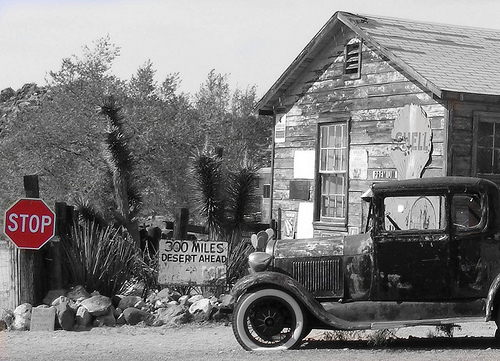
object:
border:
[51, 207, 57, 238]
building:
[253, 11, 498, 243]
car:
[230, 175, 500, 353]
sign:
[369, 102, 434, 180]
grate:
[278, 253, 345, 295]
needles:
[95, 94, 139, 217]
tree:
[0, 27, 195, 225]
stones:
[190, 300, 208, 320]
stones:
[85, 293, 109, 314]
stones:
[155, 288, 171, 302]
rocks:
[1, 82, 50, 114]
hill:
[1, 81, 218, 228]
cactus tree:
[98, 94, 143, 223]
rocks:
[5, 299, 38, 330]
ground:
[0, 320, 497, 359]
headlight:
[247, 251, 270, 272]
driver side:
[364, 176, 499, 304]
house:
[236, 8, 499, 263]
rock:
[78, 294, 116, 316]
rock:
[118, 306, 143, 328]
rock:
[152, 303, 193, 326]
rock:
[187, 295, 215, 322]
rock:
[8, 299, 33, 330]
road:
[0, 318, 499, 358]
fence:
[9, 173, 352, 312]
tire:
[223, 276, 314, 351]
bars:
[316, 120, 347, 174]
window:
[313, 115, 346, 225]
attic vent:
[344, 39, 359, 79]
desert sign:
[155, 239, 229, 286]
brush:
[69, 218, 285, 298]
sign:
[4, 197, 56, 250]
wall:
[251, 287, 278, 293]